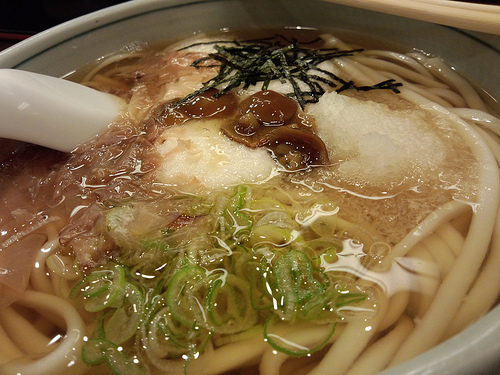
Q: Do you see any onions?
A: Yes, there is an onion.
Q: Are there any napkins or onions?
A: Yes, there is an onion.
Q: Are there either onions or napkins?
A: Yes, there is an onion.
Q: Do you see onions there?
A: Yes, there is an onion.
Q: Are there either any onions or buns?
A: Yes, there is an onion.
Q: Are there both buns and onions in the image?
A: No, there is an onion but no buns.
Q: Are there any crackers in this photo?
A: No, there are no crackers.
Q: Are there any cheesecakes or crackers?
A: No, there are no crackers or cheesecakes.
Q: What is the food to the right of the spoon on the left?
A: The food is a mushroom.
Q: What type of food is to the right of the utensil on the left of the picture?
A: The food is a mushroom.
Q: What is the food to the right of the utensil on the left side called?
A: The food is a mushroom.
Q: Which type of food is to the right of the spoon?
A: The food is a mushroom.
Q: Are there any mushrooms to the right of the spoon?
A: Yes, there is a mushroom to the right of the spoon.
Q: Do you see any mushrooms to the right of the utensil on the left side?
A: Yes, there is a mushroom to the right of the spoon.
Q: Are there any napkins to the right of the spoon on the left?
A: No, there is a mushroom to the right of the spoon.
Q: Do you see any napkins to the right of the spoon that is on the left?
A: No, there is a mushroom to the right of the spoon.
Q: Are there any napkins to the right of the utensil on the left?
A: No, there is a mushroom to the right of the spoon.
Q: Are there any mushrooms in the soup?
A: Yes, there is a mushroom in the soup.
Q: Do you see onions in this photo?
A: Yes, there are onions.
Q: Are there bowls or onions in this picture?
A: Yes, there are onions.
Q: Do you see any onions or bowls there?
A: Yes, there are onions.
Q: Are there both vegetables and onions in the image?
A: Yes, there are both onions and a vegetable.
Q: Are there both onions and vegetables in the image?
A: Yes, there are both onions and a vegetable.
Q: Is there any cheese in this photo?
A: No, there is no cheese.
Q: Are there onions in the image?
A: Yes, there is an onion.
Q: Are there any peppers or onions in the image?
A: Yes, there is an onion.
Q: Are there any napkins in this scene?
A: No, there are no napkins.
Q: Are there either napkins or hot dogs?
A: No, there are no napkins or hot dogs.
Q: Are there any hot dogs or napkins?
A: No, there are no napkins or hot dogs.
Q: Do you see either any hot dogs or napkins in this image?
A: No, there are no napkins or hot dogs.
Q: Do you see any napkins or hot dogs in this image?
A: No, there are no napkins or hot dogs.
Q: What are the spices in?
A: The spices are in the soup.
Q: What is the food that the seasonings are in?
A: The food is soup.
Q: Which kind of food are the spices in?
A: The seasonings are in the soup.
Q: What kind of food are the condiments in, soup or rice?
A: The condiments are in soup.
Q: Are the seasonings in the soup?
A: Yes, the seasonings are in the soup.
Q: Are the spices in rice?
A: No, the spices are in the soup.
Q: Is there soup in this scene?
A: Yes, there is soup.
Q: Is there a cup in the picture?
A: No, there are no cups.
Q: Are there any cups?
A: No, there are no cups.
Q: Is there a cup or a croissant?
A: No, there are no cups or croissants.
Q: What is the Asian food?
A: The food is soup.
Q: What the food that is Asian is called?
A: The food is soup.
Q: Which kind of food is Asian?
A: The food is soup.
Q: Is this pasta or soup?
A: This is soup.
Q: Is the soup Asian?
A: Yes, the soup is asian.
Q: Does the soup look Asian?
A: Yes, the soup is asian.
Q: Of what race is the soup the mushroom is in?
A: The soup is asian.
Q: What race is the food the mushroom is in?
A: The soup is asian.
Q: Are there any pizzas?
A: No, there are no pizzas.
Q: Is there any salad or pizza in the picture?
A: No, there are no pizzas or salad.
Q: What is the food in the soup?
A: The food is a mushroom.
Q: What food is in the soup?
A: The food is a mushroom.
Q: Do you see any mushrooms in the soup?
A: Yes, there is a mushroom in the soup.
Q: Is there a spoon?
A: Yes, there is a spoon.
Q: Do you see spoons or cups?
A: Yes, there is a spoon.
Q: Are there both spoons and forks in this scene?
A: No, there is a spoon but no forks.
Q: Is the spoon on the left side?
A: Yes, the spoon is on the left of the image.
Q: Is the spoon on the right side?
A: No, the spoon is on the left of the image.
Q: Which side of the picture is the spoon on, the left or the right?
A: The spoon is on the left of the image.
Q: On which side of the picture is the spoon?
A: The spoon is on the left of the image.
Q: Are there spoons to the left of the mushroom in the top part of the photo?
A: Yes, there is a spoon to the left of the mushroom.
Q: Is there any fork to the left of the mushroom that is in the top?
A: No, there is a spoon to the left of the mushroom.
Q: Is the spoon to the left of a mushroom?
A: Yes, the spoon is to the left of a mushroom.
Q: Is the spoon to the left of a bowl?
A: No, the spoon is to the left of a mushroom.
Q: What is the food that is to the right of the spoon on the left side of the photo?
A: The food is a mushroom.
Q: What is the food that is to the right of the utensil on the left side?
A: The food is a mushroom.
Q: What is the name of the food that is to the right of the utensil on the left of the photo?
A: The food is a mushroom.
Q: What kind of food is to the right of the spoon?
A: The food is a mushroom.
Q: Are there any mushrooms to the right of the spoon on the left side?
A: Yes, there is a mushroom to the right of the spoon.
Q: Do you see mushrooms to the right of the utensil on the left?
A: Yes, there is a mushroom to the right of the spoon.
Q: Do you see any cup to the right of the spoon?
A: No, there is a mushroom to the right of the spoon.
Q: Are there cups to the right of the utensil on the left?
A: No, there is a mushroom to the right of the spoon.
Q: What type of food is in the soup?
A: The food is a mushroom.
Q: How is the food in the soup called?
A: The food is a mushroom.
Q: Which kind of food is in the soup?
A: The food is a mushroom.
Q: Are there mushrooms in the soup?
A: Yes, there is a mushroom in the soup.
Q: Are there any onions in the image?
A: Yes, there is an onion.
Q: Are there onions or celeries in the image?
A: Yes, there is an onion.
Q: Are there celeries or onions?
A: Yes, there is an onion.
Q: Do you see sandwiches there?
A: No, there are no sandwiches.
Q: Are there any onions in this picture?
A: Yes, there is an onion.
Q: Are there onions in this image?
A: Yes, there is an onion.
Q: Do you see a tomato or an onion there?
A: Yes, there is an onion.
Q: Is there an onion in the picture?
A: Yes, there are onions.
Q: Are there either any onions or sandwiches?
A: Yes, there are onions.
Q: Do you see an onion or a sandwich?
A: Yes, there are onions.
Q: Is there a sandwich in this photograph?
A: No, there are no sandwiches.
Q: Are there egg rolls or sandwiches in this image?
A: No, there are no sandwiches or egg rolls.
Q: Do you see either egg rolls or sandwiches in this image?
A: No, there are no sandwiches or egg rolls.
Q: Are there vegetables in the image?
A: Yes, there are vegetables.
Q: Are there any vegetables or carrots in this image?
A: Yes, there are vegetables.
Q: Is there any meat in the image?
A: No, there is no meat.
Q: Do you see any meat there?
A: No, there is no meat.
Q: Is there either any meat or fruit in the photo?
A: No, there are no meat or fruits.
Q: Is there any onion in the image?
A: Yes, there is an onion.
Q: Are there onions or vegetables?
A: Yes, there is an onion.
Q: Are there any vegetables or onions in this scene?
A: Yes, there is an onion.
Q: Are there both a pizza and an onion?
A: No, there is an onion but no pizzas.